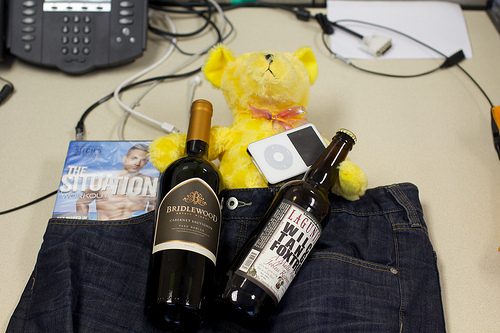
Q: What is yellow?
A: The bear.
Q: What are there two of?
A: Wine bottles.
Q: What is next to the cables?
A: Telephone.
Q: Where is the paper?
A: Under the cables.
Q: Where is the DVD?
A: In pocket.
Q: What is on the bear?
A: An electronic device.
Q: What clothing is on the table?
A: Jeans.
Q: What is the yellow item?
A: Stuffed animal.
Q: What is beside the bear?
A: Workout dvd.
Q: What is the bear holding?
A: Ipod.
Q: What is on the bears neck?
A: Ribbon.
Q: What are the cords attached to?
A: Phone.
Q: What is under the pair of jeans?
A: Table.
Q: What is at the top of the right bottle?
A: Cap.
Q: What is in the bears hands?
A: Bottles.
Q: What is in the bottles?
A: Wine.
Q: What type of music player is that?
A: MP3.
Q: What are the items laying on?
A: Table.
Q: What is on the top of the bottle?
A: Cap.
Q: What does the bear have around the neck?
A: Bow tie.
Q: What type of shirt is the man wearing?
A: No shirt.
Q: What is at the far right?
A: A mouse.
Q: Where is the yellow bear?
A: Under the jeans.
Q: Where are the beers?
A: On the jeans.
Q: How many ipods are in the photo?
A: One.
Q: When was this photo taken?
A: During the day.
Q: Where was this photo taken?
A: On a desk.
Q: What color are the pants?
A: Blue.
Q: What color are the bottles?
A: Brown.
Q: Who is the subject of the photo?
A: The objects on the desk.